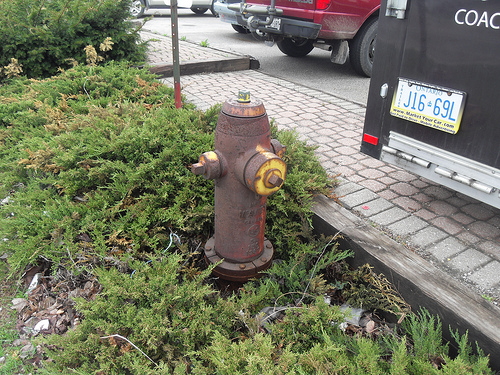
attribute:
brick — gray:
[425, 237, 469, 262]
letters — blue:
[402, 91, 454, 121]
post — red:
[170, 0, 182, 107]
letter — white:
[448, 6, 464, 31]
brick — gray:
[156, 24, 498, 289]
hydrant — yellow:
[138, 69, 338, 293]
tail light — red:
[311, 0, 333, 20]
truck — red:
[236, 0, 379, 72]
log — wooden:
[329, 265, 479, 346]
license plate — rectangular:
[389, 72, 467, 137]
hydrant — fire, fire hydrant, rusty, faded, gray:
[189, 87, 286, 278]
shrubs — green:
[3, 2, 496, 374]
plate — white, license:
[376, 95, 482, 143]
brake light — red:
[362, 132, 379, 146]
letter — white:
[462, 10, 479, 30]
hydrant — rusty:
[153, 84, 304, 283]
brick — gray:
[336, 187, 381, 210]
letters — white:
[453, 7, 498, 27]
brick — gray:
[385, 214, 427, 239]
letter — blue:
[401, 90, 412, 108]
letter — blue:
[411, 90, 418, 111]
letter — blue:
[416, 90, 426, 112]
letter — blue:
[434, 94, 443, 119]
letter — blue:
[442, 97, 449, 119]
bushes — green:
[0, 59, 498, 374]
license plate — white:
[387, 69, 470, 145]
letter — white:
[453, 6, 470, 27]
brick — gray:
[348, 199, 390, 213]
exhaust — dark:
[311, 39, 333, 51]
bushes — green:
[6, 7, 205, 290]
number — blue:
[430, 95, 445, 117]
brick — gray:
[472, 243, 499, 295]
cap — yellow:
[253, 159, 285, 191]